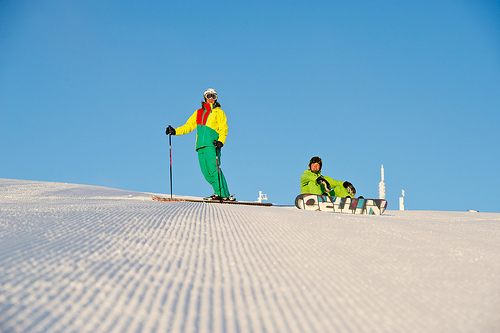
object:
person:
[173, 87, 230, 205]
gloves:
[207, 139, 226, 149]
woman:
[164, 88, 239, 201]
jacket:
[175, 102, 227, 148]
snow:
[1, 214, 498, 331]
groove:
[183, 197, 207, 331]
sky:
[0, 1, 499, 91]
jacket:
[300, 170, 356, 204]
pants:
[195, 146, 230, 199]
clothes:
[177, 105, 228, 195]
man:
[299, 155, 359, 214]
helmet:
[203, 88, 218, 100]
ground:
[0, 209, 500, 330]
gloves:
[159, 125, 179, 137]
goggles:
[204, 93, 219, 100]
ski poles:
[168, 125, 176, 201]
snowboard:
[293, 191, 391, 217]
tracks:
[111, 219, 200, 330]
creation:
[395, 187, 410, 211]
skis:
[152, 111, 253, 207]